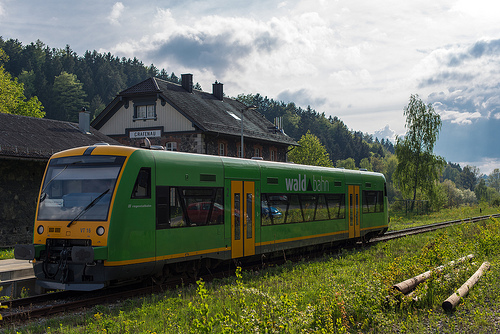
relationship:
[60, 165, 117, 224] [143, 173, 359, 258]
windshield of train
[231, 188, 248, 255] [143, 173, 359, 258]
doors of train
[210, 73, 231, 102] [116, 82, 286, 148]
chimney of building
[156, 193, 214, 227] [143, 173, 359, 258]
window on train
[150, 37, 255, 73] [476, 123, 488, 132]
cloud in sky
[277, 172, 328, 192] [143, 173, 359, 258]
writing on train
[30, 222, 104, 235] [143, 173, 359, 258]
headlights of train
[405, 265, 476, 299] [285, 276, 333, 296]
logs in grass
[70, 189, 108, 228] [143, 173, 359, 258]
wiper of train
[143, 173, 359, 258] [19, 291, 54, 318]
train on railroad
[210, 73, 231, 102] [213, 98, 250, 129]
chimney on roof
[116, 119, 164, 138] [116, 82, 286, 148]
sign on building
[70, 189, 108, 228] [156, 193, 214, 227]
wiper on window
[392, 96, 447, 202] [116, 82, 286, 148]
tree behind building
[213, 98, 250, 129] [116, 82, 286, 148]
roof of building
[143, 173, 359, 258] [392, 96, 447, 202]
train near tree